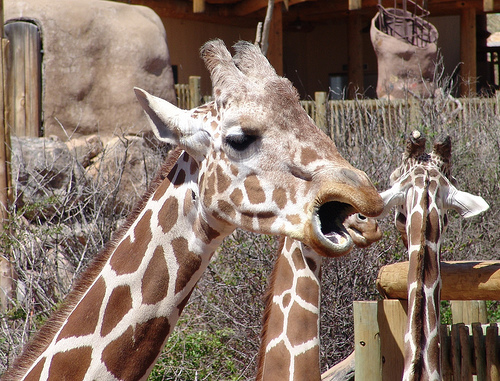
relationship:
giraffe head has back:
[375, 127, 489, 250] [402, 140, 449, 233]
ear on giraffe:
[131, 85, 209, 154] [3, 40, 383, 374]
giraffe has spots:
[3, 40, 383, 374] [21, 86, 297, 380]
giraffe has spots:
[375, 128, 488, 380] [391, 156, 453, 381]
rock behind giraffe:
[2, 2, 174, 140] [3, 40, 383, 374]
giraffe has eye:
[3, 40, 383, 374] [223, 126, 261, 159]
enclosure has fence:
[10, 76, 497, 379] [171, 75, 499, 148]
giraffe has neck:
[3, 40, 383, 374] [12, 105, 221, 378]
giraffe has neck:
[375, 128, 488, 380] [401, 183, 444, 381]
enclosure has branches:
[10, 76, 497, 379] [9, 50, 496, 347]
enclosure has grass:
[10, 76, 497, 379] [141, 324, 257, 379]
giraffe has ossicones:
[3, 40, 383, 374] [196, 38, 279, 92]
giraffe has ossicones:
[375, 128, 488, 380] [399, 128, 452, 167]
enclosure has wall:
[10, 76, 497, 379] [9, 138, 500, 318]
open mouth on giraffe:
[311, 192, 385, 254] [3, 40, 383, 374]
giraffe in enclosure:
[0, 36, 386, 381] [10, 76, 497, 379]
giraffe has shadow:
[375, 128, 488, 380] [436, 255, 497, 298]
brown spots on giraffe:
[14, 88, 327, 379] [3, 40, 383, 374]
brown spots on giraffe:
[254, 237, 324, 380] [257, 237, 329, 381]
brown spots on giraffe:
[392, 155, 455, 380] [375, 128, 488, 380]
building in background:
[116, 0, 495, 97] [2, 3, 500, 139]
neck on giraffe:
[12, 105, 221, 378] [3, 40, 383, 374]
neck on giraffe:
[401, 183, 444, 381] [375, 128, 488, 380]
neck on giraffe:
[258, 237, 322, 380] [257, 237, 329, 381]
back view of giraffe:
[373, 126, 486, 381] [375, 128, 488, 380]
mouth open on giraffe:
[311, 192, 385, 254] [3, 40, 383, 374]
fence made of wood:
[171, 75, 499, 148] [177, 74, 498, 144]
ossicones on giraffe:
[196, 38, 279, 92] [3, 40, 383, 374]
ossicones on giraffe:
[399, 128, 452, 167] [375, 128, 488, 380]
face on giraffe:
[132, 35, 384, 259] [3, 40, 383, 374]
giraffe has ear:
[3, 40, 383, 374] [132, 84, 213, 161]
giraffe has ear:
[375, 128, 488, 380] [441, 184, 489, 222]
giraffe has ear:
[375, 128, 488, 380] [375, 176, 405, 219]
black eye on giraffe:
[223, 126, 261, 159] [3, 40, 383, 374]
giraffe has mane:
[3, 40, 383, 374] [3, 143, 183, 380]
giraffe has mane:
[375, 128, 488, 380] [409, 173, 429, 381]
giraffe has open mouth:
[3, 40, 383, 374] [311, 192, 385, 254]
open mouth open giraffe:
[311, 192, 385, 254] [3, 40, 383, 374]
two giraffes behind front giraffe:
[251, 131, 499, 379] [3, 40, 383, 374]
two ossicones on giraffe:
[196, 38, 279, 92] [3, 40, 383, 374]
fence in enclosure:
[171, 75, 499, 148] [10, 76, 497, 379]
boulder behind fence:
[361, 12, 455, 97] [171, 75, 499, 148]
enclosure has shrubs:
[10, 76, 497, 379] [9, 50, 496, 347]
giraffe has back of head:
[375, 128, 488, 380] [375, 127, 489, 250]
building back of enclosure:
[116, 0, 495, 97] [10, 76, 497, 379]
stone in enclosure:
[2, 2, 174, 140] [10, 76, 497, 379]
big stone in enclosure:
[2, 2, 174, 140] [10, 76, 497, 379]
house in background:
[116, 0, 495, 97] [2, 3, 500, 139]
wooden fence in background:
[171, 75, 499, 148] [2, 3, 500, 139]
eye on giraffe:
[223, 126, 261, 159] [3, 40, 383, 374]